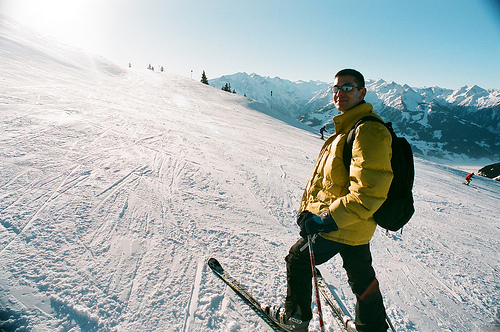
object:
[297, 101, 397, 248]
jacket